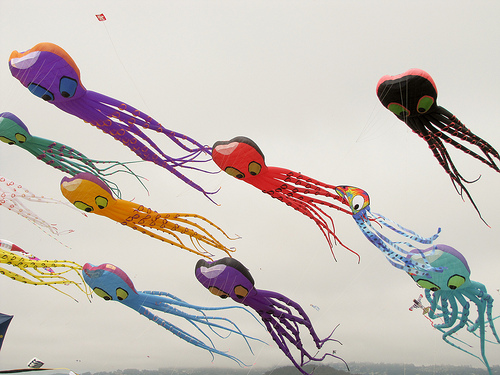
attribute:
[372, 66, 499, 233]
octopus — black, red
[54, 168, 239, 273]
octopus — yellow - orange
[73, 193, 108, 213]
eyes — green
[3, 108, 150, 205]
octopus kite — green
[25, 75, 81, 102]
eyes — blue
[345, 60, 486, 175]
kite — black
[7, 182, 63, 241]
tentacles — pink, red, white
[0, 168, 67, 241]
kite — octopus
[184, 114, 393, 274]
kite — purple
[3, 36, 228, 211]
octopus kite — orange, blue, purple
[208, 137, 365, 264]
squid — red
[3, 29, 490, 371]
octopus kites — multicolored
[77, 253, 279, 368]
kite — blue, pink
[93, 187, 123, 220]
eyes — yellow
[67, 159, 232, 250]
kite — octopus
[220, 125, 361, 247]
octopus kite — red, black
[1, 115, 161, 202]
kite — green, octopus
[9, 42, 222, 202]
kite — purple, orange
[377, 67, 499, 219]
kite — yellow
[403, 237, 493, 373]
kite — turquoise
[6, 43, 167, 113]
kite — light blue, octopus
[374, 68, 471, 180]
kite — light purple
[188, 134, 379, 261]
kite — red, black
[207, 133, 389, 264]
squid — red, flying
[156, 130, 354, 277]
squid — red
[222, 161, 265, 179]
eyes — orange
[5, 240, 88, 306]
octopus — yellow